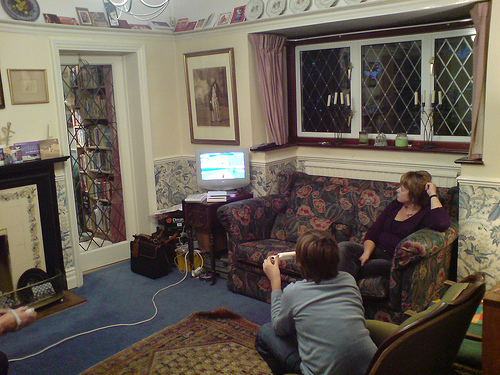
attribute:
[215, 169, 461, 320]
couch — floral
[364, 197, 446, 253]
shirt — purple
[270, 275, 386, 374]
shirt — grey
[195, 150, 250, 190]
television — white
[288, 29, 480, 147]
window — here, framed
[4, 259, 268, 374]
floor —   white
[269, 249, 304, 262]
controller — white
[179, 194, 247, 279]
table — wooden, dark brown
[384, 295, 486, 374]
back — leather, brown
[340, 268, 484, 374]
chair — green, wooden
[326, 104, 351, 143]
candle holder — fancy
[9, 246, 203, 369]
cord — white, long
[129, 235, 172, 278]
bag — black, brown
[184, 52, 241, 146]
frame — gold